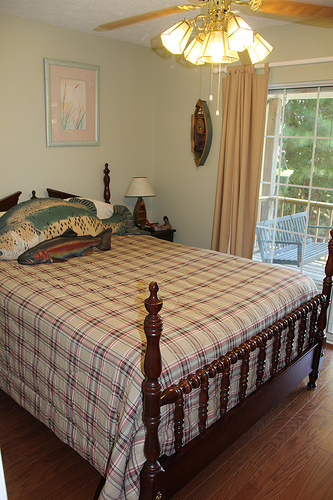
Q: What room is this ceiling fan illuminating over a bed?
A: Bedroom.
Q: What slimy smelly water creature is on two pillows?
A: Fish.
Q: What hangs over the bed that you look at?
A: Picture.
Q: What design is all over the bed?
A: Checkered.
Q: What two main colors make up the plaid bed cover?
A: Red and tan.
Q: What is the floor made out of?
A: Wood.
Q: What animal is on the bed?
A: Fish.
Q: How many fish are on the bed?
A: Two.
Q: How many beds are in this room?
A: One.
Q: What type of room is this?
A: Bedroom.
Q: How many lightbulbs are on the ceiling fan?
A: Five.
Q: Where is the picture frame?
A: Wall.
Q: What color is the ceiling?
A: White.